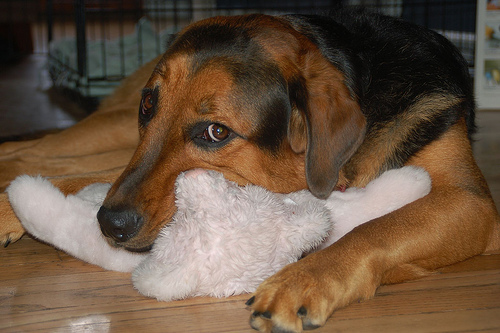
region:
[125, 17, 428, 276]
a dog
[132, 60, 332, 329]
a dog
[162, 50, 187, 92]
a dog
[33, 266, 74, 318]
Natural wood flooring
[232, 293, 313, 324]
Claws of a large dog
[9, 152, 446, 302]
Stuffed animal dog toy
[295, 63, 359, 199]
Ear of a large dog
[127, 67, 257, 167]
Dog's eyes looking at photographer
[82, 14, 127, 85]
Steel fence in the background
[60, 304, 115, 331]
Reflection of a window on the floor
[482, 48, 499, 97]
Picture hung on the wall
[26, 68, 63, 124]
Reflection of sunlight on the floor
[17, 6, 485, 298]
Large dog laying on his play toy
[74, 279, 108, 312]
part of a floor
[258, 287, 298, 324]
edge of a paw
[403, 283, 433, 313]
part of a floor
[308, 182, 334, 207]
edge of an ear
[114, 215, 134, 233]
edge of a nose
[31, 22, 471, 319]
The dog is lying down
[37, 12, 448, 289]
The dog is brown and black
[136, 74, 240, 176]
The dog has brown eyes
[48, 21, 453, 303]
The dog has its head on a stuffed animal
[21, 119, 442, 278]
The stuffed animal is white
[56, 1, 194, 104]
Black barred gate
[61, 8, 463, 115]
The gate is behind the dog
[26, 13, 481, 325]
The dog is lying on wood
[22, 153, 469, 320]
The flooring is wood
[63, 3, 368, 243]
The dog is looking at the camera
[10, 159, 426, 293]
a dog cuddling its teddy bear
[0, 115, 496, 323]
a brown wood floor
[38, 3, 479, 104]
a pen behind a dog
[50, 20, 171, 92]
white cloth lining a pen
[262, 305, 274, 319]
a black claw on a dog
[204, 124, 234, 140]
a brown eye of a dog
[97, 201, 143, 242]
a wet black dog nose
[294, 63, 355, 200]
a brown dog ear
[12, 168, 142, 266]
the outstretched arm of a teddy bear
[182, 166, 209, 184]
the nose of a teddy bear